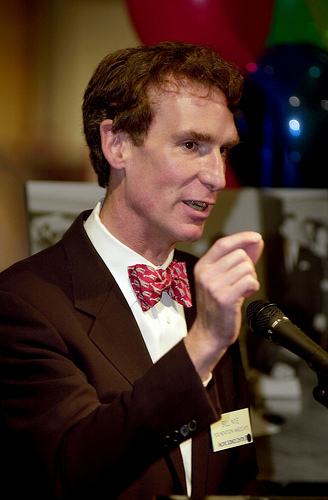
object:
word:
[221, 418, 230, 427]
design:
[128, 259, 193, 312]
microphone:
[246, 297, 328, 377]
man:
[0, 41, 265, 499]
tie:
[127, 260, 193, 310]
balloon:
[228, 45, 327, 186]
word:
[214, 423, 249, 436]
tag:
[211, 404, 254, 451]